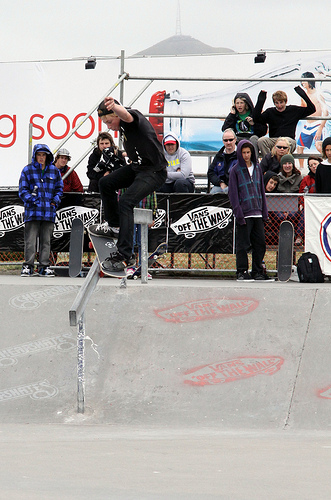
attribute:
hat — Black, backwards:
[91, 90, 141, 118]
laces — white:
[94, 219, 108, 233]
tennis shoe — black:
[87, 222, 118, 238]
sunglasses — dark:
[222, 136, 236, 142]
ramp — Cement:
[202, 285, 252, 319]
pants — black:
[97, 164, 168, 259]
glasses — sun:
[221, 137, 235, 142]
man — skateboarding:
[78, 97, 166, 273]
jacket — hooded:
[230, 136, 262, 173]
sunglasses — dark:
[274, 143, 288, 150]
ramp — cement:
[105, 289, 202, 341]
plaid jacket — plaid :
[19, 143, 62, 220]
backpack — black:
[301, 249, 315, 271]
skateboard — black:
[84, 223, 130, 290]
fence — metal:
[280, 205, 288, 213]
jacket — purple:
[230, 137, 264, 209]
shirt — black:
[121, 118, 161, 169]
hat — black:
[94, 97, 127, 110]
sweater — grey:
[163, 128, 193, 183]